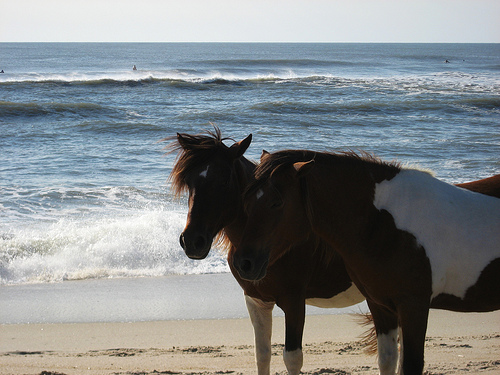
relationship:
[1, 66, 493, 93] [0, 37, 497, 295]
waves int water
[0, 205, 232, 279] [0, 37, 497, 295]
waves int water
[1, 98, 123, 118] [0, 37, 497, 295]
waves int water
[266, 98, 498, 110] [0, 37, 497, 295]
waves int water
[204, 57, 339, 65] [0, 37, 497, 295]
waves int water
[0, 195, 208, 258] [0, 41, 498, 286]
waves in ocean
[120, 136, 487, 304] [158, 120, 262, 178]
horse has mane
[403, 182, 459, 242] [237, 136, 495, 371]
whit spot on horse